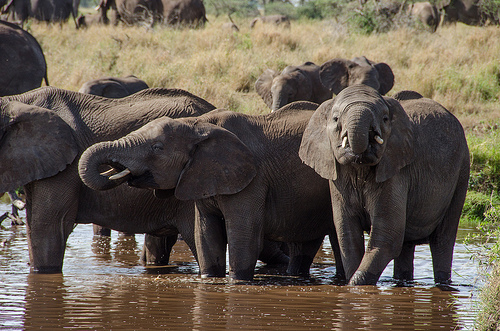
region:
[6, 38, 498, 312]
a group of elephants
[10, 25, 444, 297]
a group of elephants in water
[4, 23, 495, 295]
a group of elephants near water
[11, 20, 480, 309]
a group of elephants near grass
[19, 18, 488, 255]
a group of elephants inside the water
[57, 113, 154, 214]
trunk of the elephant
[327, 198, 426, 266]
legs of the elephant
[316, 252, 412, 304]
legs of the elephant inside water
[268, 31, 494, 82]
green grass on back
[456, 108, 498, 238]
a part of the green grass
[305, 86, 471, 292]
elephant in a lake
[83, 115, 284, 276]
elephant in a lake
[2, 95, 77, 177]
ear of an elephant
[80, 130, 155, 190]
trunk on an elephant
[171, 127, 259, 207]
ear of an elephant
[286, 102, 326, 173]
ear of an elephant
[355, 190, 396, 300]
leg of an elephant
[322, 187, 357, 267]
leg of an elephant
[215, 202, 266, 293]
leg of an elephant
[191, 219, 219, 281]
leg of an elephant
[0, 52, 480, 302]
elephants bathing in river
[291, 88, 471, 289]
elephant in river facing forward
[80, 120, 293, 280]
elephant with curled trunk and tusks visible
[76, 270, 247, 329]
shallow, muddy river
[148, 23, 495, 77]
grassy riverbank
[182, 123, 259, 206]
large, floppy elephant ear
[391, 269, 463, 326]
reflection of elephant legs in river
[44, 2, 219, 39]
elephants grazing on grassy bank near river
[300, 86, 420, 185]
head of adult elephant facing forward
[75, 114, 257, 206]
profile of head of elephant facing left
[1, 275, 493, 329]
The water is brown.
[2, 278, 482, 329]
The water looks very dirty.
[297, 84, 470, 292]
Elephant looking at camera.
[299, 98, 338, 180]
Left ear of elephant looking a camera.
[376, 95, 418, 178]
Right ear of elephant looking a camera.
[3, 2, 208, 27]
Group of elephants in the distance on the left.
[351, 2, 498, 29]
Group of elephants in the distance on the right.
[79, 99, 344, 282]
Elephant with it's eyes shut, in the water.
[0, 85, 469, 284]
Three elephants in the water.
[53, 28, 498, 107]
Tall grass behind the elephants.